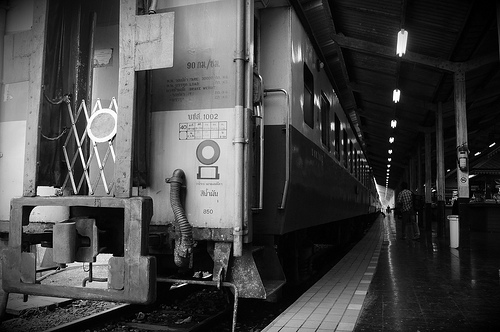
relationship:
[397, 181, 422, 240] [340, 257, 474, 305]
man on hallway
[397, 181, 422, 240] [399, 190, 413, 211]
man wearing plaid shirt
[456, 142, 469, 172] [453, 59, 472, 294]
fire exstinguisher on post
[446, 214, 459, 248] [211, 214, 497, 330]
trash can on platform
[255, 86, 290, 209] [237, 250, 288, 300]
rail above step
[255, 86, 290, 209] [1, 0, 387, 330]
rail on train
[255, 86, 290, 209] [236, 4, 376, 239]
rail on side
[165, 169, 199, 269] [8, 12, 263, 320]
coil on back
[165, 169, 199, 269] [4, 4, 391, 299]
coil on train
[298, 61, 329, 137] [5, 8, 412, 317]
window on train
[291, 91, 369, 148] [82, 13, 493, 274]
window on train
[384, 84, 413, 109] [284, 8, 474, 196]
light on ceiling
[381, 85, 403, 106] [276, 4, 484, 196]
light on ceiling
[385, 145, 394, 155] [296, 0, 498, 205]
light on ceiling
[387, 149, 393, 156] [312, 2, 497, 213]
light on ceiling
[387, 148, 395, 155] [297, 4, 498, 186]
light on ceiling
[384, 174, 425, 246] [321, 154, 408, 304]
man walking through hallway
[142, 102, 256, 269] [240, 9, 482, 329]
electrical system displayed in building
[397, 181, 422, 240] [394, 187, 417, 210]
man has on plaid shirt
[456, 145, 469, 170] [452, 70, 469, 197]
fire exstinguisher hanging from post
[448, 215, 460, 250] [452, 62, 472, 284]
trash can behind a pole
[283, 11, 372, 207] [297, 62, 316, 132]
wall has window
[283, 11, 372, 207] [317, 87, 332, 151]
wall has window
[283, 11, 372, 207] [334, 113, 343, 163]
wall has window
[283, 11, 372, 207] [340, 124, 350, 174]
wall has window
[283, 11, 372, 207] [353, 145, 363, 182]
wall has window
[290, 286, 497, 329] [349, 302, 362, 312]
floor has tile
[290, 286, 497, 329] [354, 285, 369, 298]
floor has tile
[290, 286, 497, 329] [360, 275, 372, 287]
floor has tile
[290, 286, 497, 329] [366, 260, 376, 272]
floor has tile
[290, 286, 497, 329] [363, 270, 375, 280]
floor has tile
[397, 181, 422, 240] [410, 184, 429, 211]
man carrying a backpack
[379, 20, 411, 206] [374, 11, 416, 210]
lights that are in ceiling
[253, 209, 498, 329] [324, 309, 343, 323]
floor has tile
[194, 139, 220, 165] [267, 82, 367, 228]
circle on train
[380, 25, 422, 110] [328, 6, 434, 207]
lights on ceiling